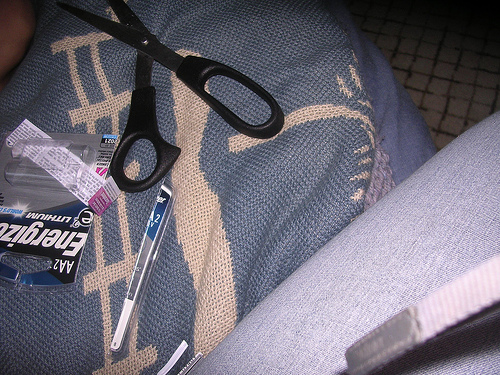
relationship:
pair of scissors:
[92, 14, 284, 193] [80, 13, 284, 191]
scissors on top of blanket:
[80, 13, 284, 191] [12, 7, 384, 356]